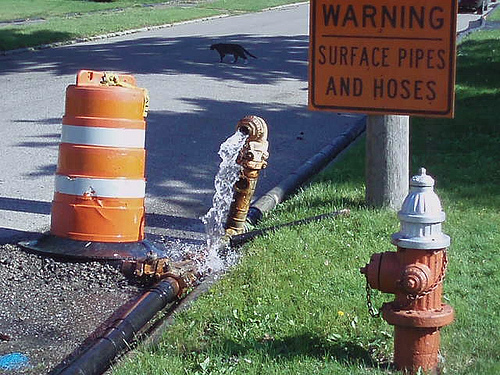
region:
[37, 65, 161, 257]
a large work zone orange cone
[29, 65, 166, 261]
an orange cone with white stripes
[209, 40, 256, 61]
a dark cat with white boots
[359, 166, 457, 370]
silver and red fire hydrant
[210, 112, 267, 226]
a vertical pipe spewing water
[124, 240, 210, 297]
connecting pipe leaking water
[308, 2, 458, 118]
a water leak warning sign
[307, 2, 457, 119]
an orange sign with black writing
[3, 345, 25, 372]
blue spray painted dot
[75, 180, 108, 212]
dent in working zone cone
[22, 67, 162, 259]
Orange and white traffic cone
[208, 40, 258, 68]
Black cat with white paws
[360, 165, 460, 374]
Red and white fire extinguisher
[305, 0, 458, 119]
Orange warning sign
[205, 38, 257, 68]
Cat crossing a road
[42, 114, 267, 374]
Broken water piping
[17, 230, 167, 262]
Black rubber base of a traffic cone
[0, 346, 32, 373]
Blue paint in the gravel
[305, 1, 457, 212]
Orange sign on a wood post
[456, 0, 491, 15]
Vehicle on the road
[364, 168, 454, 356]
red fire hydrant with a white cap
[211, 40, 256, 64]
a black cat crossing the road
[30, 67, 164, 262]
an orange and white construction barrel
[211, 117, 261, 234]
a pipe sticking out of the ground with gushing water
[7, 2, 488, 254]
a road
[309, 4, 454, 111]
an orange warning sign on the telephone pole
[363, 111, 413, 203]
a gray telephone pole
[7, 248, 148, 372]
gravel where road is dug up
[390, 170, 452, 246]
white cap on the fire hydrant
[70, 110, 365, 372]
surface pipes along the road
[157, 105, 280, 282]
water is pouring out of the pipes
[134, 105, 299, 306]
the pipes in this area burst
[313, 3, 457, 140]
a caution sign is set on the post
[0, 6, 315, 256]
a road is in this area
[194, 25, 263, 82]
a cat is crossing the road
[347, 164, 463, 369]
a fire hydrant sits in the grass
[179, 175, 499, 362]
the grass is green in color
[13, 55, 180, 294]
the caution cone is orange and white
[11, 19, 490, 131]
this shadow belongs to a nearby tree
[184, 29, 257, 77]
the cat is walking the path of the shadow